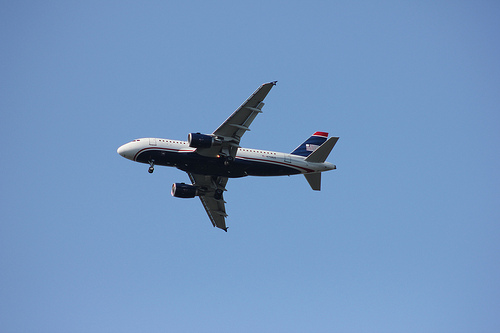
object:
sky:
[0, 140, 79, 167]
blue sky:
[120, 16, 384, 59]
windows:
[137, 140, 141, 141]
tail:
[303, 136, 340, 192]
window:
[159, 139, 162, 141]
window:
[166, 140, 168, 142]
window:
[172, 141, 175, 143]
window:
[184, 143, 186, 145]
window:
[240, 149, 242, 151]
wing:
[187, 172, 229, 232]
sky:
[386, 0, 499, 35]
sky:
[340, 90, 412, 110]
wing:
[194, 80, 278, 158]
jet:
[116, 81, 339, 231]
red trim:
[313, 131, 328, 137]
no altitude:
[337, 146, 397, 178]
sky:
[2, 3, 82, 30]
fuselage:
[117, 137, 337, 178]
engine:
[188, 132, 223, 149]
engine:
[171, 182, 200, 198]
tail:
[290, 131, 329, 157]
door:
[149, 138, 157, 146]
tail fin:
[290, 131, 329, 158]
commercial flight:
[116, 80, 340, 232]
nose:
[116, 146, 131, 157]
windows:
[274, 153, 276, 155]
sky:
[55, 68, 427, 285]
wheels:
[226, 156, 234, 163]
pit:
[117, 137, 149, 163]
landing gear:
[148, 159, 154, 173]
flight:
[116, 80, 340, 232]